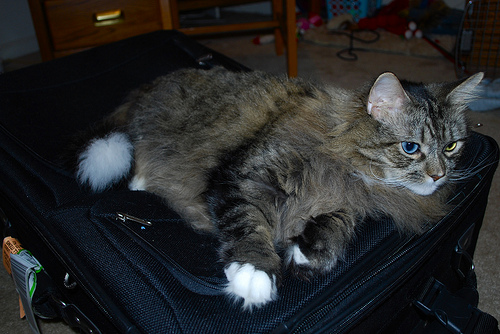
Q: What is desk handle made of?
A: Gold.